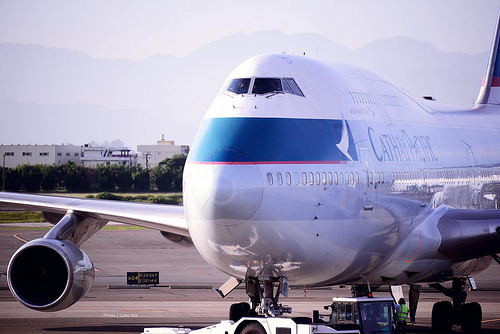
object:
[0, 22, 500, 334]
jumbojet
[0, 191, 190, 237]
wing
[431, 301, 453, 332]
wheels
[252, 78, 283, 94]
windows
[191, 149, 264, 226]
nose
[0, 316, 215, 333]
tarmac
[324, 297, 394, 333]
vehicle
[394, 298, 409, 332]
man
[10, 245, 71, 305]
propeller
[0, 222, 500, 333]
road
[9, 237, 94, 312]
engine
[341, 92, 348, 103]
windows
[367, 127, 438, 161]
writing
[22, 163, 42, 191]
trees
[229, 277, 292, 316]
gear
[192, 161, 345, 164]
stripe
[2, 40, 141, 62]
mountains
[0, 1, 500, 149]
background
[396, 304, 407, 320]
safetyvest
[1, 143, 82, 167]
buildings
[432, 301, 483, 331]
landinggear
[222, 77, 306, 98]
cockpit